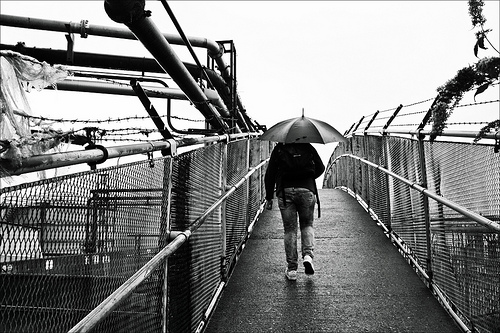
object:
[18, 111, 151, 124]
wire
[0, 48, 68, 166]
plastic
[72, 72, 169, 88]
wire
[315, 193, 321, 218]
strap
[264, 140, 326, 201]
sweater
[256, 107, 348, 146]
umbrella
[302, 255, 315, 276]
shoe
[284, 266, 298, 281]
white shoe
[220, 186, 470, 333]
ground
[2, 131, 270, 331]
fence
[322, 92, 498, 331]
fence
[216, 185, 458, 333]
ramp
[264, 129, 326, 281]
person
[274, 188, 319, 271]
jeans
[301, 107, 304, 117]
point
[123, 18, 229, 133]
barbed wire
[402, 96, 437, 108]
barbed wire